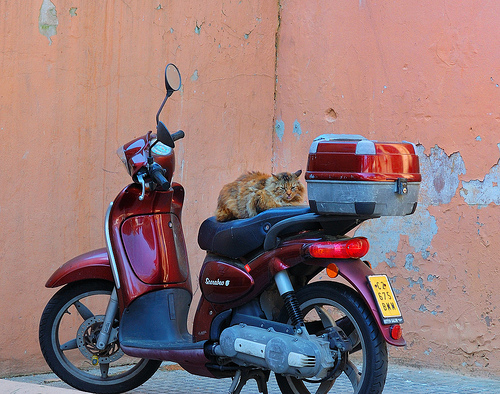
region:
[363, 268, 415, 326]
License plate on a scooter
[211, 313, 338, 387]
Drive line on a scooter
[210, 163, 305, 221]
Long-haired cat sitting on a scooter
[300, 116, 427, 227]
Luggage compartment for a scooter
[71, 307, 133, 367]
Disc brakes on a scooter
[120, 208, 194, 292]
Locking door on a scooter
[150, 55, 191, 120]
Rearview mirror on a scooter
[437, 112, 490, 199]
Paint peeling off the wall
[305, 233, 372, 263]
Stoplight on a scooter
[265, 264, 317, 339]
Shock absorber on a scooter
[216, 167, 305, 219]
a brown cat resting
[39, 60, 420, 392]
a parked red motorcycle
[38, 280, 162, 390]
a motorcycle front tire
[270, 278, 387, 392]
a motorcycle rear tire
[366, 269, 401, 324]
a yellow and black license plate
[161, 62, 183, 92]
a motorcycle rear view mirror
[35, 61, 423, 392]
a cat sleeping on motorcycle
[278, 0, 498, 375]
a peeling painted wall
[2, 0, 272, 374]
a peeling painted wall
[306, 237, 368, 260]
a motorcycle brake light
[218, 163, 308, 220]
cat sitting on top of moped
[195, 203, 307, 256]
black seat of moped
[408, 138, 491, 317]
peach building with peeling paint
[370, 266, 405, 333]
yellow license plate on back of moped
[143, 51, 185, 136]
mirror attached to handlebars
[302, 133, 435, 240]
case attached to back of moped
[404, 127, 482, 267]
peeling area of concrete walls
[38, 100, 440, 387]
moped parked in front of building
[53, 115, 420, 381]
red moped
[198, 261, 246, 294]
white lettering on side of moped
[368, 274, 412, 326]
The yellow license plate on the scooter.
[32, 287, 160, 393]
The front wheel of the scooter.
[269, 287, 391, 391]
The back wheel of the scooter.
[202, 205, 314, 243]
The black seat of the scooter.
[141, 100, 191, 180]
The handle bars of the scooter.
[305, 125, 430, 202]
The storage compartment on the back of the scooter.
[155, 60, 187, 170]
The side view mirrors.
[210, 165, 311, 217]
The cat on the black seat of the scooter.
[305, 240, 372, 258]
The back red brake light.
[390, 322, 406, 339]
The small red circle under the license plate.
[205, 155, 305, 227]
a cat on a scooter seat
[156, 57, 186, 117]
the rear view mirror of a scooter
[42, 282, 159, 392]
a wheel of a scooter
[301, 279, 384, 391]
a wheel of a scooter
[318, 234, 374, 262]
the tail light of a scooter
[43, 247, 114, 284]
the fender of a scooter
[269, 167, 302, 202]
a head of a cat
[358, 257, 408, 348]
the fender of a scooter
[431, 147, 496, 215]
chips off a wall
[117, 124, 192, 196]
the handle bars of a scooter